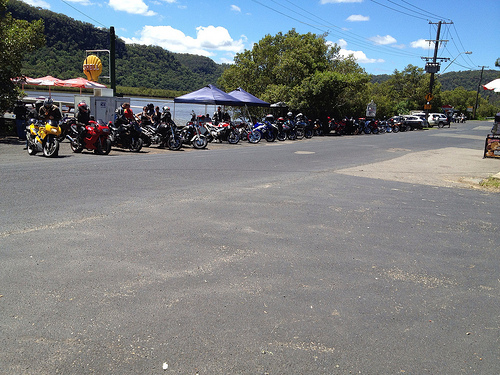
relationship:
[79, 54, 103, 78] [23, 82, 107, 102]
sign over gas station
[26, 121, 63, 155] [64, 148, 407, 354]
motorcycle on street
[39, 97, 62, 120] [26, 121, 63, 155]
rider next to motorcycle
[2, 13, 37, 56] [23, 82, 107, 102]
tree behind gas station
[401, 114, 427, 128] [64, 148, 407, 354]
vehicle parked on street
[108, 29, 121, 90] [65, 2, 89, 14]
pole supporting power line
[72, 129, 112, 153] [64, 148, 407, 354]
motorcycle on street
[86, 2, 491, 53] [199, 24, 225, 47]
sky has cloud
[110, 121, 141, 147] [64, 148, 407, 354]
motorcycle on street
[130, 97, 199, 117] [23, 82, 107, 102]
lake behind gas station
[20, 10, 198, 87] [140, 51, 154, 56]
foliage on hill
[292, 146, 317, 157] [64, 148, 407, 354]
sewage drain in street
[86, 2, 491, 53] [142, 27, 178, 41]
sky has cloud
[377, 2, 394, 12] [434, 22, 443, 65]
power line on pole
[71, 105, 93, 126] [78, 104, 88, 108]
rider has helmet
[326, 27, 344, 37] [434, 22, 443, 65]
power line on pole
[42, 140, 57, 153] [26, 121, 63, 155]
wheel on motorcycle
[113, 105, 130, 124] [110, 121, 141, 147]
rider on motorcycle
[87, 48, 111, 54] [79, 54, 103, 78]
pole supporting sign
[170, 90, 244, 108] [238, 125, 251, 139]
tarp behind motorcycle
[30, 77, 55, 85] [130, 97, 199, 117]
umbrella near lake